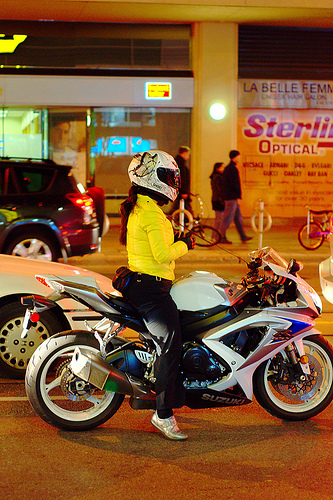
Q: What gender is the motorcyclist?
A: Female.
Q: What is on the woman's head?
A: Helmet.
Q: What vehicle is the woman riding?
A: Motorcycle.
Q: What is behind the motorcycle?
A: Car.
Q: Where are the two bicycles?
A: Background sidewalk.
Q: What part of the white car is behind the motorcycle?
A: Front end.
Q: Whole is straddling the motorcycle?
A: Young woman yellow jacket.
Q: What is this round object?
A: Rear wheel.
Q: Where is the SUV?
A: Opposite lane.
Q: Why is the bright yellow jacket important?
A: Well seen by traffic.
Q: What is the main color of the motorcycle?
A: It is white.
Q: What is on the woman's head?
A: A helmet.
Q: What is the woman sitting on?
A: A motorcycle.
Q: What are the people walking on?
A: A sidewalk.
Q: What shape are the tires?
A: Round.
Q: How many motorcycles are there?
A: One.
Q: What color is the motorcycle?
A: White.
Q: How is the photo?
A: Clear.